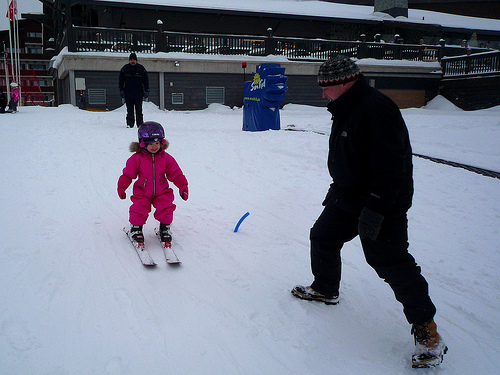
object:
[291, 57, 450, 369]
man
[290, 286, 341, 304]
boot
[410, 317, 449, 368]
boot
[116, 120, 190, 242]
child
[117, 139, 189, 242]
clothing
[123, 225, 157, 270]
ski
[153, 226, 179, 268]
ski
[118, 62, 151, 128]
clothing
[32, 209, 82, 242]
ground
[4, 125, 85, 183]
snow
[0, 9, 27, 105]
poles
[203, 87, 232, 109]
window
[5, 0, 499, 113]
building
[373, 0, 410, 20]
chimney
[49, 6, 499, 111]
house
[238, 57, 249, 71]
light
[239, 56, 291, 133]
machinery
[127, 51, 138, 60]
cap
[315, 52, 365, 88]
cap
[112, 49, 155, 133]
man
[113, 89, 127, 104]
gloves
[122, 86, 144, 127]
pants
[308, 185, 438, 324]
pants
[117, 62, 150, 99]
jacket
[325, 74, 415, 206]
jacket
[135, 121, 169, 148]
helmet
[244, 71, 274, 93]
sign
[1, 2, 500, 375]
skate park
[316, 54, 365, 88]
beanie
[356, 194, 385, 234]
gloves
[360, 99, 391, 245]
hand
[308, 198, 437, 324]
snow pants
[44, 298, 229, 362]
snow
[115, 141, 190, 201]
snow suit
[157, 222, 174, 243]
shoe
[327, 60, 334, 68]
dot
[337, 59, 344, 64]
dot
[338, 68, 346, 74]
dot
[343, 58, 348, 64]
dot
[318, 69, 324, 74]
dots